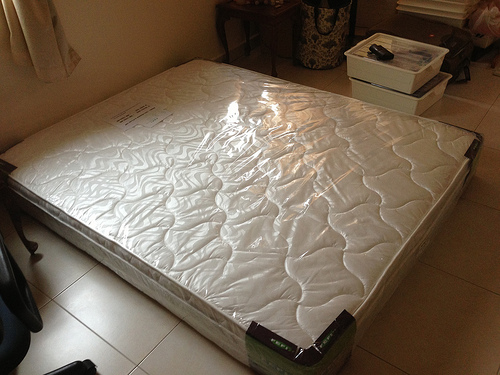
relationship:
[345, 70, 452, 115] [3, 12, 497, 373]
box on floor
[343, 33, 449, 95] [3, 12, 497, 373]
containers on floor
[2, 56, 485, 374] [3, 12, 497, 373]
mattress on floor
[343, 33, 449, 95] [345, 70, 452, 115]
containers on top of bin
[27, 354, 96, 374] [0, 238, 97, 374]
leg of chair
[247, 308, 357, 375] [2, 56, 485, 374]
edge protector on mattress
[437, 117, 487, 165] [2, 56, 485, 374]
edge protector on mattress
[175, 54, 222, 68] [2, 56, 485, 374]
edge protector on mattress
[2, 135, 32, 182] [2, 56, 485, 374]
edge protector on mattress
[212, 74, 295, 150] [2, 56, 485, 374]
reflection on plastic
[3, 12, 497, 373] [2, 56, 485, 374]
floor under mattress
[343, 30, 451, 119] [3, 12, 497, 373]
containers on floor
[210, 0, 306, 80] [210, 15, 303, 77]
table has legs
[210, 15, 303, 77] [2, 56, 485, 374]
legs next to mattress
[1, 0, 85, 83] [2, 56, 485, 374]
curtain above mattress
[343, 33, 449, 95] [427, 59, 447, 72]
containers has handle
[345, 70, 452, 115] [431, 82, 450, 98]
container has handle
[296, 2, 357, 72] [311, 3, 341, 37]
bag has handle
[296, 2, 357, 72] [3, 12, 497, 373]
bag on floor